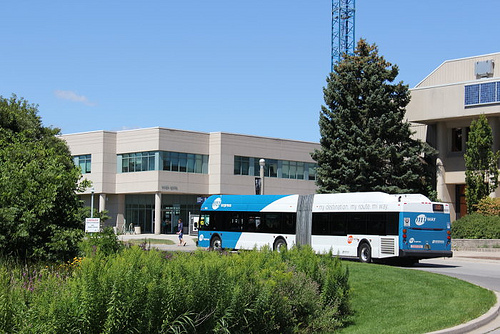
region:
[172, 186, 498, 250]
blue and white transit bus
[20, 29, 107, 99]
white clouds in blue sky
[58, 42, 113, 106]
white clouds in blue sky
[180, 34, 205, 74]
white clouds in blue sky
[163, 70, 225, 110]
white clouds in blue sky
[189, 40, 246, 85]
white clouds in blue sky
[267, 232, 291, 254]
Wheel of a bus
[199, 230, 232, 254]
Wheel of a bus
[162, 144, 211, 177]
Window of a building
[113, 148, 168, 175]
Window of a building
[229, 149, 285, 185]
Window of a building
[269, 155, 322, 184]
Window of a building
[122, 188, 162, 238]
Window of a building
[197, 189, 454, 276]
the long bus is making a turn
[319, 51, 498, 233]
trees are grown in front of the building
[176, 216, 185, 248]
the person is walking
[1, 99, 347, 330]
plants grown with green leaves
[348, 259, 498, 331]
green grasses neatly maintained on the platform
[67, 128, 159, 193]
windows on the side of the building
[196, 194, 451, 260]
the bus has black windows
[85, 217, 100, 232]
a sign board with white background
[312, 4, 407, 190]
a metal tower behind the tree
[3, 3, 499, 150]
a sky with cloud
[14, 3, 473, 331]
scene during the day time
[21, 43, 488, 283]
a scene at a gray building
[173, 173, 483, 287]
a white and blue bus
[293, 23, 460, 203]
a large tree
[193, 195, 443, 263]
A blue and white bus in front of the tree.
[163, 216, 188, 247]
A person walking in front of the building.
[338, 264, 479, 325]
The grass is green.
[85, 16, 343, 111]
The sky is clear and blue.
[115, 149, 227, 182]
Glass windows on the building.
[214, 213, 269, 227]
Windows on the bus.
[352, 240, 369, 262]
The back wheel of the bus.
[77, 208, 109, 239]
A white sign on the gray pole.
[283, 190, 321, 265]
The bus has a gray strap in the middle on the side.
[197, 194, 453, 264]
the bus is blue and white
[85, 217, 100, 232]
the sign is white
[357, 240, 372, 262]
the tire is black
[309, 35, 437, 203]
the tree is tall and green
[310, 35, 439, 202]
the tree is full and green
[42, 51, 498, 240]
the building has a lot of windows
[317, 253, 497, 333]
the grass is green and short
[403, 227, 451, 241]
the tail lights are red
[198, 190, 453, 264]
a blue and white public service bus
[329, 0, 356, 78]
a black metal tower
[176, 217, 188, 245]
a pedestrian walking on sidewalk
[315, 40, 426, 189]
a tall evergreen tree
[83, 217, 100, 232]
a white informational sign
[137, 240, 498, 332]
a circular street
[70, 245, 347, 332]
a large green bush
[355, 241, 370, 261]
a black rear bus tire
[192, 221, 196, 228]
a bus sideview mirror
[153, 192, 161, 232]
a building support column